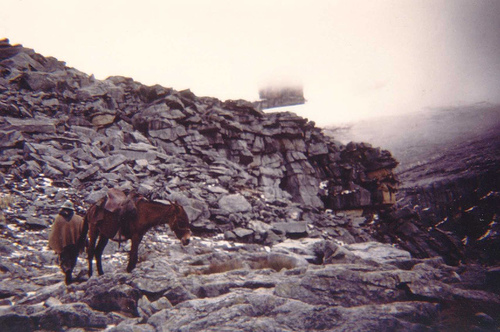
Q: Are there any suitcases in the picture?
A: No, there are no suitcases.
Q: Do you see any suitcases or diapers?
A: No, there are no suitcases or diapers.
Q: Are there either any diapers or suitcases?
A: No, there are no suitcases or diapers.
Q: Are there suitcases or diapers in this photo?
A: No, there are no suitcases or diapers.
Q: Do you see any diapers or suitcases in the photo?
A: No, there are no suitcases or diapers.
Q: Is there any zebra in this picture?
A: No, there are no zebras.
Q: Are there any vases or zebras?
A: No, there are no zebras or vases.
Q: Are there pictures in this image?
A: No, there are no pictures.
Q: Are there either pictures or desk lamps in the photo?
A: No, there are no pictures or desk lamps.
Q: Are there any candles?
A: No, there are no candles.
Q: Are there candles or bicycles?
A: No, there are no candles or bicycles.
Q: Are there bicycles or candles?
A: No, there are no candles or bicycles.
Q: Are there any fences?
A: No, there are no fences.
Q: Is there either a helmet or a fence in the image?
A: No, there are no fences or helmets.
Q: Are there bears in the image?
A: No, there are no bears.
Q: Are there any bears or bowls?
A: No, there are no bears or bowls.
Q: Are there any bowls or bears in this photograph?
A: No, there are no bears or bowls.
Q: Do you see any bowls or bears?
A: No, there are no bears or bowls.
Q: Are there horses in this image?
A: Yes, there is a horse.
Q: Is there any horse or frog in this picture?
A: Yes, there is a horse.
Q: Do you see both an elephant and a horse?
A: No, there is a horse but no elephants.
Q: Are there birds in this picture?
A: No, there are no birds.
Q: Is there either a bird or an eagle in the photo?
A: No, there are no birds or eagles.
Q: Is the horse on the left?
A: Yes, the horse is on the left of the image.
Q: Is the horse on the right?
A: No, the horse is on the left of the image.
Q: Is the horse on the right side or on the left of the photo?
A: The horse is on the left of the image.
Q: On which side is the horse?
A: The horse is on the left of the image.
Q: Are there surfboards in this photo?
A: No, there are no surfboards.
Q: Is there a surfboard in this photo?
A: No, there are no surfboards.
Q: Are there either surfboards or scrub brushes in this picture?
A: No, there are no surfboards or scrub brushes.